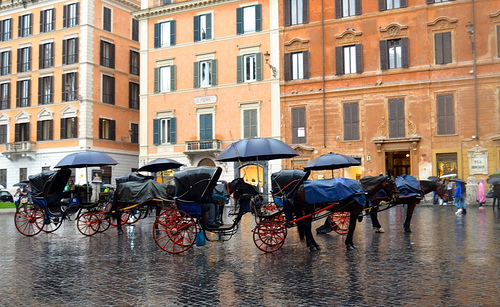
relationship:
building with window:
[137, 7, 498, 178] [197, 58, 212, 87]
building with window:
[137, 7, 498, 178] [160, 65, 174, 93]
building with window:
[137, 7, 498, 178] [238, 5, 256, 32]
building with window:
[137, 7, 498, 178] [157, 23, 173, 46]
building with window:
[137, 7, 498, 178] [342, 48, 357, 75]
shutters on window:
[235, 50, 264, 87] [243, 53, 256, 75]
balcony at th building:
[1, 141, 42, 162] [0, 7, 128, 189]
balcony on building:
[182, 138, 222, 155] [131, 0, 282, 202]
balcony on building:
[182, 138, 222, 155] [0, 0, 137, 195]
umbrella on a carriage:
[218, 134, 296, 164] [195, 134, 300, 212]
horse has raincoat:
[110, 175, 180, 235] [113, 178, 169, 207]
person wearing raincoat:
[475, 176, 487, 213] [469, 173, 499, 201]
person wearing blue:
[452, 180, 465, 215] [452, 179, 462, 207]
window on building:
[154, 19, 175, 47] [131, 0, 282, 202]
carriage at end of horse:
[248, 166, 313, 256] [290, 173, 401, 255]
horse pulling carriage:
[290, 173, 401, 255] [248, 182, 298, 254]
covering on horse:
[304, 177, 369, 207] [294, 170, 400, 250]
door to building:
[200, 113, 212, 148] [130, 0, 499, 205]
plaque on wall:
[446, 130, 498, 186] [277, 0, 498, 195]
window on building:
[15, 46, 30, 74] [0, 0, 137, 195]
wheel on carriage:
[252, 211, 306, 288] [146, 167, 290, 256]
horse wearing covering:
[290, 173, 401, 255] [304, 177, 372, 207]